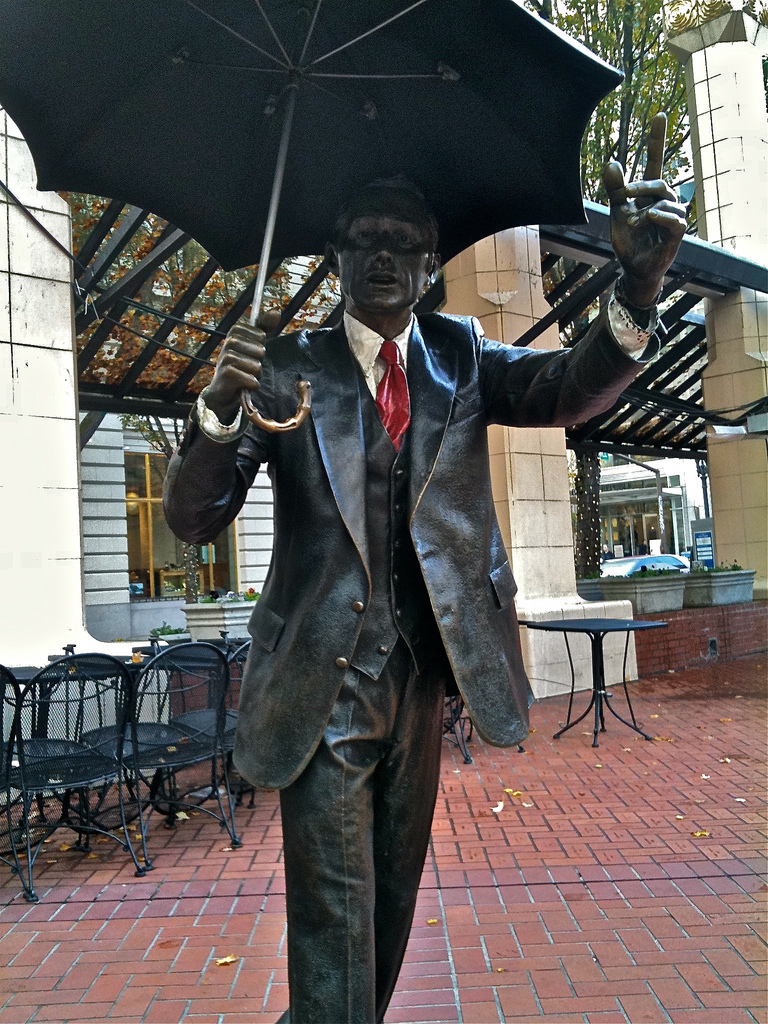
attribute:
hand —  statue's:
[200, 325, 275, 403]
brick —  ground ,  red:
[534, 939, 622, 999]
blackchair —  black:
[12, 643, 258, 906]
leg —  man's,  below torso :
[278, 638, 450, 1023]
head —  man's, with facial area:
[331, 177, 437, 316]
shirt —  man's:
[228, 304, 540, 793]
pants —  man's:
[281, 652, 448, 1022]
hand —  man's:
[185, 322, 278, 427]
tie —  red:
[377, 338, 411, 438]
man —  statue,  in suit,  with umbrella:
[164, 111, 692, 1018]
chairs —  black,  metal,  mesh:
[4, 636, 265, 893]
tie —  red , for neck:
[378, 338, 408, 433]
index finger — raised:
[642, 110, 667, 181]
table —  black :
[518, 617, 667, 748]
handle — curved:
[240, 83, 312, 435]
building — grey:
[2, 4, 463, 734]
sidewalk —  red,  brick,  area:
[5, 664, 765, 1015]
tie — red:
[376, 327, 410, 441]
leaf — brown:
[215, 953, 240, 968]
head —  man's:
[322, 168, 440, 316]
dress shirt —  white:
[337, 309, 423, 443]